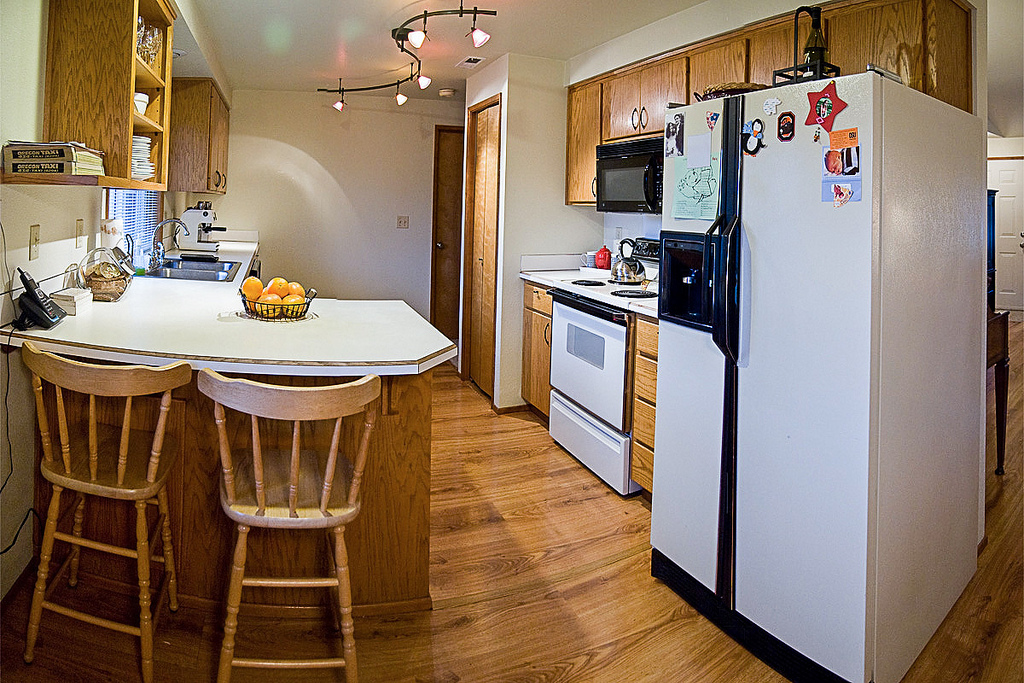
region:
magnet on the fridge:
[699, 105, 719, 144]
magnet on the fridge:
[658, 138, 678, 164]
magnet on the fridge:
[814, 142, 844, 171]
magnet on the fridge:
[819, 126, 868, 158]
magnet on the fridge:
[762, 89, 792, 119]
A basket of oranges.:
[229, 268, 324, 327]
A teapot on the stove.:
[602, 235, 653, 286]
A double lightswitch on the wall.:
[387, 207, 419, 237]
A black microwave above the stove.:
[578, 128, 671, 218]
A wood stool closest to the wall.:
[11, 334, 199, 680]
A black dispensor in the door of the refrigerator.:
[650, 223, 737, 342]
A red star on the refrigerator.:
[794, 80, 852, 139]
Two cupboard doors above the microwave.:
[596, 52, 685, 144]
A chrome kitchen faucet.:
[121, 207, 191, 278]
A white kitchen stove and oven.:
[542, 232, 657, 502]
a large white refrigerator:
[660, 97, 983, 657]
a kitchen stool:
[193, 350, 396, 667]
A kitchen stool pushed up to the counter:
[192, 350, 405, 679]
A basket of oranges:
[239, 263, 322, 325]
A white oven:
[546, 279, 636, 495]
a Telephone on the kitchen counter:
[10, 256, 64, 334]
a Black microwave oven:
[590, 129, 666, 219]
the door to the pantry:
[457, 91, 522, 402]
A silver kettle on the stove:
[609, 238, 651, 293]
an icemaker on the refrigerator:
[651, 221, 721, 335]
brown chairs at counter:
[32, 329, 435, 677]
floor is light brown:
[418, 423, 505, 668]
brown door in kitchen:
[447, 145, 523, 393]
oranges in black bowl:
[210, 238, 309, 352]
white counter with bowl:
[131, 262, 435, 384]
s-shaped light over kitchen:
[304, 22, 482, 182]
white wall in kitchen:
[257, 95, 423, 311]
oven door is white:
[529, 335, 607, 396]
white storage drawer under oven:
[526, 385, 657, 528]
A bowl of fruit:
[229, 258, 327, 325]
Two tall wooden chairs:
[5, 324, 392, 672]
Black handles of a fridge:
[687, 197, 758, 369]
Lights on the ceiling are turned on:
[305, 0, 506, 121]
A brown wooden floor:
[1, 307, 1016, 672]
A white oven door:
[535, 282, 637, 442]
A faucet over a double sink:
[133, 200, 245, 284]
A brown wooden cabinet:
[551, 61, 615, 214]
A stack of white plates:
[115, 118, 166, 192]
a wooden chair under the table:
[248, 290, 423, 607]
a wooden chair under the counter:
[24, 366, 265, 680]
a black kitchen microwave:
[544, 126, 682, 228]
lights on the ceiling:
[391, 28, 434, 93]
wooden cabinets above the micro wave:
[591, 76, 677, 131]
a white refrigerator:
[660, 110, 986, 657]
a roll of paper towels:
[98, 218, 119, 256]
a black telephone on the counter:
[13, 272, 58, 324]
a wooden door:
[435, 133, 464, 329]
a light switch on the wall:
[397, 214, 416, 228]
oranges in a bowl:
[243, 278, 310, 316]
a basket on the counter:
[97, 265, 129, 301]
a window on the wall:
[104, 181, 166, 245]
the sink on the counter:
[148, 212, 228, 280]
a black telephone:
[19, 266, 58, 323]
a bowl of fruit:
[239, 277, 316, 313]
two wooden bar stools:
[16, 342, 375, 650]